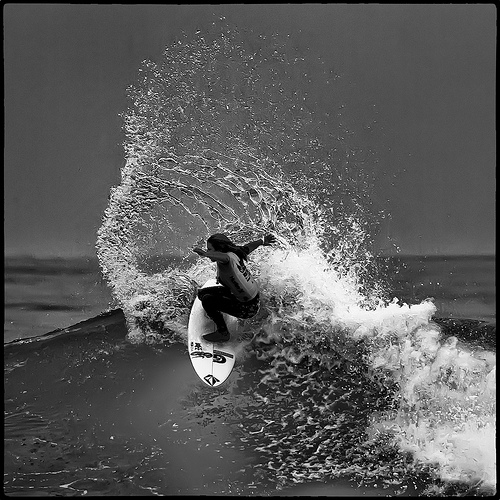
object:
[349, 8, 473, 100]
sky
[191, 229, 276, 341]
surfer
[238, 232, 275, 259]
arm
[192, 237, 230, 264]
arm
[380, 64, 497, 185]
clouds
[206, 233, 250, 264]
black hair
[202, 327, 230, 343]
shoe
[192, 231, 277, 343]
woman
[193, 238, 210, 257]
hands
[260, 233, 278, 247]
hands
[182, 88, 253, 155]
wall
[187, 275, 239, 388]
board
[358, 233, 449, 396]
ocean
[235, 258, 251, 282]
logo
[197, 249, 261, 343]
wetsuit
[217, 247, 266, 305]
top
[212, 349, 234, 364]
logos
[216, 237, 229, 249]
hair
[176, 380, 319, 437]
water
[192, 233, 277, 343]
rider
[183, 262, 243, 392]
surfboard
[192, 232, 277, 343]
wet suit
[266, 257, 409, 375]
wave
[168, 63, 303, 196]
splash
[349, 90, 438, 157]
air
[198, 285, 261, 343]
pants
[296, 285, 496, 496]
waves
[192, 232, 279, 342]
person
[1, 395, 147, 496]
ocean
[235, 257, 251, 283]
advertising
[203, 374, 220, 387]
logo